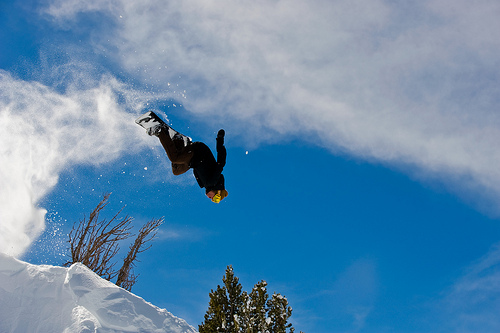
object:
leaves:
[197, 264, 296, 333]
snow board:
[134, 111, 192, 146]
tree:
[198, 264, 296, 333]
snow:
[0, 250, 198, 333]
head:
[205, 185, 228, 203]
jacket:
[192, 147, 224, 189]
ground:
[0, 251, 197, 333]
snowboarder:
[134, 111, 192, 144]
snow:
[259, 284, 266, 293]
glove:
[217, 128, 225, 138]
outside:
[1, 15, 402, 330]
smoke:
[38, 0, 500, 217]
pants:
[157, 130, 197, 175]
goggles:
[212, 190, 222, 204]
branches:
[61, 190, 165, 293]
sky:
[0, 0, 500, 333]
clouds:
[42, 0, 497, 218]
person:
[148, 124, 228, 204]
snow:
[136, 111, 162, 129]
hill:
[0, 253, 189, 333]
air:
[0, 0, 500, 333]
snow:
[0, 59, 166, 261]